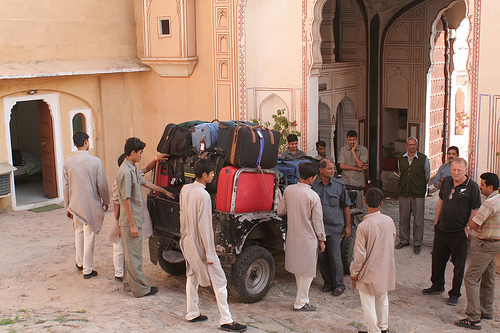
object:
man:
[178, 158, 248, 333]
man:
[60, 131, 109, 280]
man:
[454, 172, 500, 331]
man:
[115, 137, 176, 299]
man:
[421, 157, 481, 306]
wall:
[1, 0, 132, 83]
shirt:
[471, 189, 500, 240]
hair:
[193, 159, 215, 180]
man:
[275, 162, 326, 311]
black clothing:
[437, 174, 482, 233]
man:
[431, 146, 460, 189]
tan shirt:
[61, 150, 110, 235]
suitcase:
[224, 125, 280, 170]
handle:
[251, 125, 269, 130]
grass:
[0, 307, 87, 333]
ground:
[0, 219, 67, 298]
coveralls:
[114, 157, 152, 298]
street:
[122, 284, 450, 326]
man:
[337, 129, 370, 223]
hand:
[351, 142, 359, 150]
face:
[348, 138, 357, 147]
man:
[349, 187, 398, 333]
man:
[395, 135, 431, 254]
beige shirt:
[349, 210, 398, 297]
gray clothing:
[310, 177, 354, 237]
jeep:
[145, 183, 366, 304]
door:
[7, 98, 58, 206]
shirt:
[276, 182, 328, 279]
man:
[310, 158, 351, 297]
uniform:
[309, 174, 354, 288]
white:
[218, 292, 224, 309]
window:
[157, 17, 171, 36]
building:
[0, 0, 500, 214]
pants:
[183, 275, 232, 326]